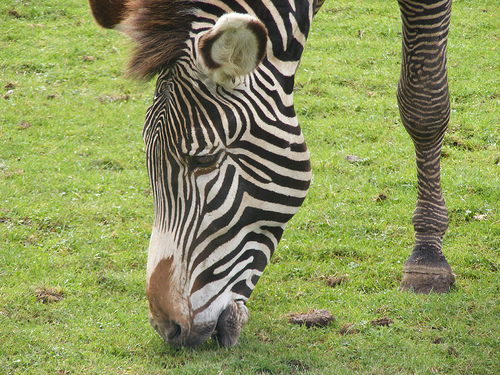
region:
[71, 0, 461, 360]
the zebra is eating grass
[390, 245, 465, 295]
the hoof of a zebra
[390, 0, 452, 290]
the leg of a zebra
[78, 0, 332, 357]
a zebra eating grass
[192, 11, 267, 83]
the ear of a zebra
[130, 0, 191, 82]
the mane of a zebra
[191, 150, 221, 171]
the eye of a zebra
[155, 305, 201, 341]
the nose of a zebra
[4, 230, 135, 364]
green grass and dirt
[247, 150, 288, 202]
the fur of a zebra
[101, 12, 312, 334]
black and white zebra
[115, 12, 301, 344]
black and white striped zebra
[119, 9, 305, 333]
black and white striped zebra eating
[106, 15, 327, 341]
black and white striped zebra eating grass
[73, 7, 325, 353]
striped zebra eating grass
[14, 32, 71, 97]
green and brown short grass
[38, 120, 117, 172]
green and brown short grass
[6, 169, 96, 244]
green and brown short grass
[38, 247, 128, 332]
green and brown short grass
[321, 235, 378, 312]
green and brown short grass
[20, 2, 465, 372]
The zebra is eating grass.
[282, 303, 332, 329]
A clump of dirt on the grass.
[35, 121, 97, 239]
The grass is green.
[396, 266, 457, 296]
The zebra has a hoof.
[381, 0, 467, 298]
The front leg of the zebra.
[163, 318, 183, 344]
A nostril on the zebra.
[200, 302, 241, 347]
The zebra has a mouth.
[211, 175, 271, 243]
The zebra has black and white stripes.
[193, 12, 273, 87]
The zebra has an ear.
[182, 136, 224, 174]
The zebra has an eye.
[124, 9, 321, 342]
zebra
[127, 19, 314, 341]
striped zebra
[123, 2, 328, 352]
black and white striped zebra grazing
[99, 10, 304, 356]
black and white striped zebra grazing on grass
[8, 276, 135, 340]
short green and yellow grass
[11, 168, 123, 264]
short green and yellow grass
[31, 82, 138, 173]
short green and yellow grass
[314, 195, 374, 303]
short green and yellow grass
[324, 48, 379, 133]
short green and yellow grass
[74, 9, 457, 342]
The zebra is grazing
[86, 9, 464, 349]
The zebra is eating the grass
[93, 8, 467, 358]
The zebra is striped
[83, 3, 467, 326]
The zebra is black and white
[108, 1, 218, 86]
The zebra has a short mane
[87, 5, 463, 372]
The zebra is standing on grass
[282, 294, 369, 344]
Dirt clumps in the grass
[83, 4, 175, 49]
The zebra has black tipped ears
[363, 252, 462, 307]
The zebra's hooves are black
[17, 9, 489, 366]
The grass is short and green